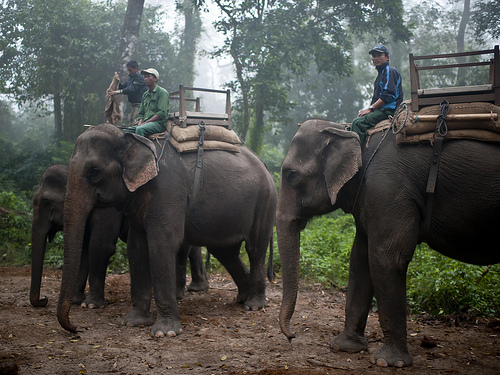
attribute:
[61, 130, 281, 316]
elephant — standing, small, big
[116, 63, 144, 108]
man — standing, sitting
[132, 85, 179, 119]
shirt — green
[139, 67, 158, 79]
hat — baseball cap, tan, navy